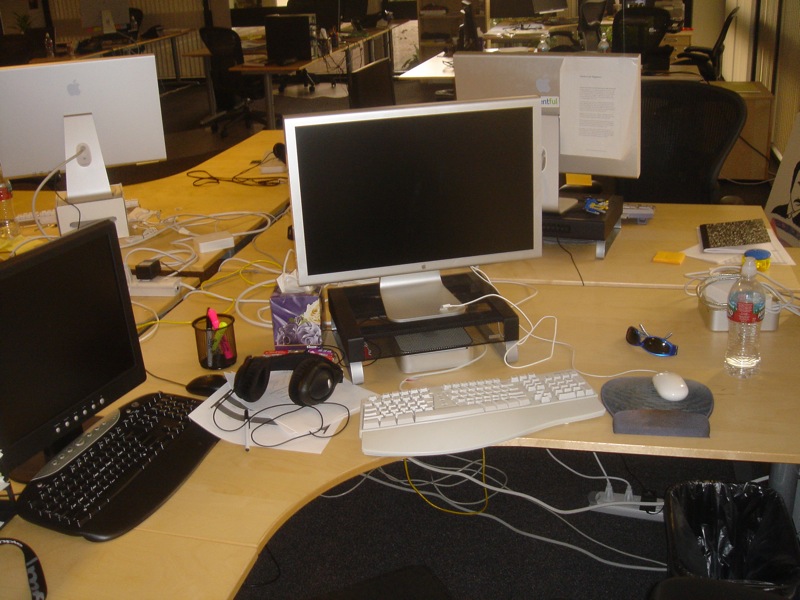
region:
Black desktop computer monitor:
[2, 216, 150, 473]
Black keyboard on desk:
[17, 390, 222, 545]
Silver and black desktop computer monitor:
[275, 95, 548, 329]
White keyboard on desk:
[363, 368, 607, 454]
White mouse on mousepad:
[651, 369, 692, 403]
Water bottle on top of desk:
[725, 255, 768, 373]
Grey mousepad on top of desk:
[599, 371, 719, 443]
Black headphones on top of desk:
[229, 344, 347, 414]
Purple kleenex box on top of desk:
[266, 267, 328, 353]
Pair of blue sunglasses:
[622, 319, 681, 362]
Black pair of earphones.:
[232, 353, 345, 407]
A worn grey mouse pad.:
[602, 370, 716, 444]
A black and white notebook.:
[698, 219, 773, 256]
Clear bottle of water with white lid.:
[724, 261, 762, 373]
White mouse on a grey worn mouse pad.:
[652, 370, 689, 403]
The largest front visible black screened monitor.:
[280, 94, 545, 289]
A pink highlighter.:
[206, 308, 235, 361]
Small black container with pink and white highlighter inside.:
[188, 315, 239, 371]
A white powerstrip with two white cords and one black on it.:
[586, 487, 670, 521]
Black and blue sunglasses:
[618, 319, 682, 359]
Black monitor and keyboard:
[0, 216, 228, 545]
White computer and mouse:
[355, 366, 691, 467]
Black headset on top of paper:
[186, 344, 383, 460]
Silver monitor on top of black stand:
[277, 91, 544, 384]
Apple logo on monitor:
[62, 75, 84, 99]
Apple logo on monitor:
[532, 69, 557, 95]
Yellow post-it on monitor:
[563, 172, 595, 189]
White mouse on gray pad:
[595, 366, 718, 441]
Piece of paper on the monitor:
[553, 52, 639, 165]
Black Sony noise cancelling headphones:
[236, 352, 353, 406]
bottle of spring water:
[720, 259, 765, 384]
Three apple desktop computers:
[1, 51, 655, 270]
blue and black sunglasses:
[628, 320, 680, 356]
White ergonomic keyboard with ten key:
[360, 375, 609, 442]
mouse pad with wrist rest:
[601, 373, 721, 442]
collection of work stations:
[3, 7, 797, 593]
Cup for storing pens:
[196, 307, 244, 371]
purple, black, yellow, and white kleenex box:
[271, 275, 328, 348]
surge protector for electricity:
[591, 484, 666, 528]